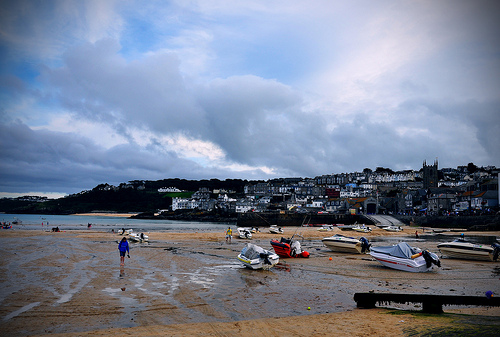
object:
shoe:
[127, 255, 131, 258]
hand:
[128, 252, 130, 254]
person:
[118, 237, 130, 266]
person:
[360, 236, 369, 254]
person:
[41, 222, 44, 228]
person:
[46, 221, 49, 228]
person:
[138, 233, 144, 245]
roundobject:
[328, 257, 332, 261]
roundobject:
[307, 307, 311, 311]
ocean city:
[0, 156, 500, 228]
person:
[254, 226, 259, 233]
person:
[111, 228, 115, 234]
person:
[225, 227, 233, 244]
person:
[279, 236, 288, 243]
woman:
[118, 237, 130, 266]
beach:
[0, 222, 499, 335]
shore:
[1, 222, 500, 337]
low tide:
[0, 233, 500, 337]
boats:
[316, 224, 335, 232]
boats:
[237, 226, 253, 239]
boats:
[302, 223, 344, 227]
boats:
[382, 225, 404, 232]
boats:
[371, 232, 500, 244]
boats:
[127, 232, 149, 242]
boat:
[368, 242, 440, 273]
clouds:
[0, 0, 497, 197]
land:
[0, 212, 500, 337]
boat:
[240, 226, 256, 233]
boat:
[437, 238, 471, 260]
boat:
[236, 243, 280, 271]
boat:
[269, 238, 310, 259]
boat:
[321, 234, 371, 254]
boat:
[352, 223, 372, 232]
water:
[0, 212, 231, 225]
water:
[0, 233, 500, 337]